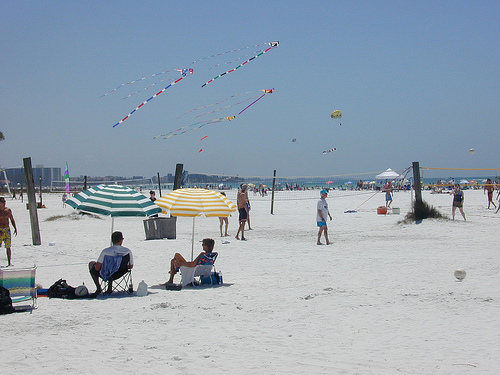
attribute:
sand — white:
[250, 269, 356, 341]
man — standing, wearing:
[224, 163, 269, 263]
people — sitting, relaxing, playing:
[46, 178, 276, 317]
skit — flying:
[100, 31, 212, 136]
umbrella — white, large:
[370, 149, 423, 184]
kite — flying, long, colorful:
[155, 20, 301, 82]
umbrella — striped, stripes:
[145, 147, 250, 229]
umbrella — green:
[77, 165, 164, 223]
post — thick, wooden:
[387, 133, 438, 250]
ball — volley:
[432, 235, 484, 286]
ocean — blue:
[296, 173, 350, 194]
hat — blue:
[311, 178, 336, 202]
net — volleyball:
[399, 157, 499, 205]